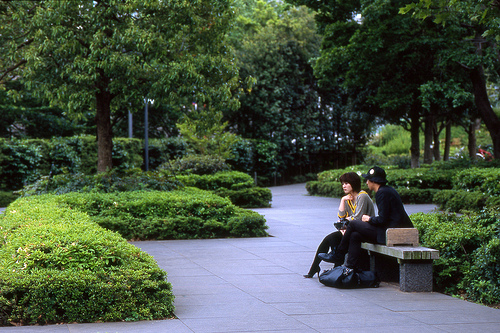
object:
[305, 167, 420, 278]
man and woman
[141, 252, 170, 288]
angled edges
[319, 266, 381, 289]
black bag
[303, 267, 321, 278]
high-heeled shoe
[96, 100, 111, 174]
tree trunk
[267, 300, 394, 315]
cement block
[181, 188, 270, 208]
green hedge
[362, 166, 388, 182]
black hat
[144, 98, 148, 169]
light pole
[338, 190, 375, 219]
gray sweater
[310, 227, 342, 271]
black pants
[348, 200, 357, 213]
yellow trim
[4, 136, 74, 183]
lush bush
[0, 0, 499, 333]
park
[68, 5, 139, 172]
tree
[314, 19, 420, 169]
tree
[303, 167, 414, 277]
people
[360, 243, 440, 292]
bench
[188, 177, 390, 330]
cement walkway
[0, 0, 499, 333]
landscaping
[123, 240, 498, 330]
cement sidewalk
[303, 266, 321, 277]
black shoes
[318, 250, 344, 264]
black shoes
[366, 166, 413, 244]
man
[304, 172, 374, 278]
woman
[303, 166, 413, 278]
two people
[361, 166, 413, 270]
person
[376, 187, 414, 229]
shirt